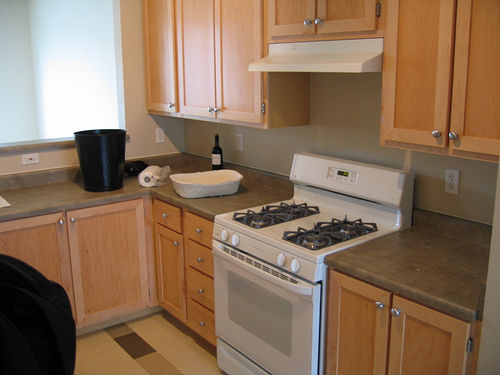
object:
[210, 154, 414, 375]
gas range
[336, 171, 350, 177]
led display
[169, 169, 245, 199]
container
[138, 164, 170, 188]
towels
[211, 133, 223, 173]
bottle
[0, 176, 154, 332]
counter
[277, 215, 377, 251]
burners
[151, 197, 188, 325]
cabinet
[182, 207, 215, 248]
drawers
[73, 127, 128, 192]
bucket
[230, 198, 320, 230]
burner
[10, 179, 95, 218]
countertop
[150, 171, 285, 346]
counter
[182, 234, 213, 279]
drawers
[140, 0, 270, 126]
cabinets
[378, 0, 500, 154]
cabinets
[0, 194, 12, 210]
sink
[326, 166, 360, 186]
display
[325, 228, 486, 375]
counter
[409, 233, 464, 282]
top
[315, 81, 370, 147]
wall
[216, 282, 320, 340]
door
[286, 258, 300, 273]
knobs